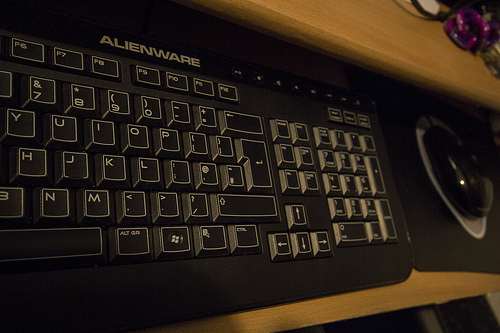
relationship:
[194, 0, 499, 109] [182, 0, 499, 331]
shelf on desk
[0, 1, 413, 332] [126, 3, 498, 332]
keyboard kept on table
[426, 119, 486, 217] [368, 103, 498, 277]
mouse kept on mouse pad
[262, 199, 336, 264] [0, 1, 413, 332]
arrow keys on keyboard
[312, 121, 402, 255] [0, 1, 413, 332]
numeric keys on keyboard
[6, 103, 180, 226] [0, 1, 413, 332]
alphabet keys on keyboard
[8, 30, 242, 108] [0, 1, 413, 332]
function keys on keyboard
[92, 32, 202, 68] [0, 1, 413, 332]
brand name on keyboard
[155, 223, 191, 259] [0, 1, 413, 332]
key on keyboard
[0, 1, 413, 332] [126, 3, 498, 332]
keyboard on table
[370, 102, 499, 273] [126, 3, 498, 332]
mousepad on table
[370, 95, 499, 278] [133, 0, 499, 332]
mousepad on computer table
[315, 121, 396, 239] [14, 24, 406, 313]
number keys on keyboard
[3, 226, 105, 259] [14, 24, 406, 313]
space bar on keyboard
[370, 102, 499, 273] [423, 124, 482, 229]
mousepad under mouse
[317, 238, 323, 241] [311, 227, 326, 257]
arrow on key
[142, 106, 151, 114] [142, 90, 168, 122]
number on key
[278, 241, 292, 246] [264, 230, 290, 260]
arrow on key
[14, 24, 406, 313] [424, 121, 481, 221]
keyboard next to mouse